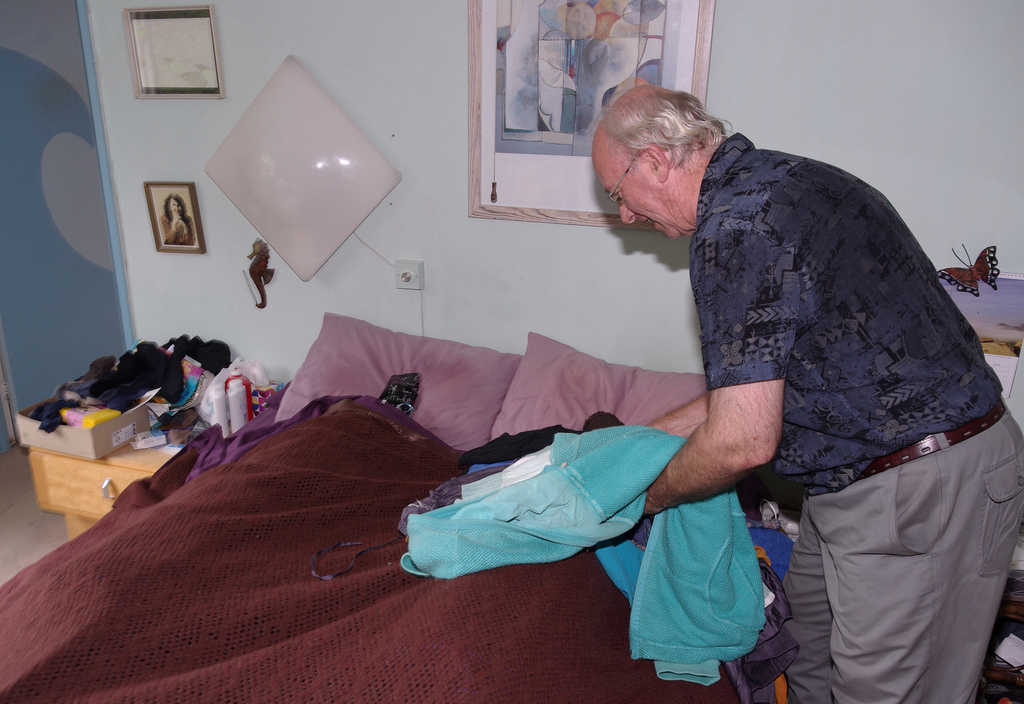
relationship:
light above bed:
[198, 57, 418, 274] [5, 293, 813, 701]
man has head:
[525, 76, 1020, 701] [577, 79, 724, 220]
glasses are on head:
[588, 157, 650, 209] [577, 79, 724, 220]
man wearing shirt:
[563, 84, 991, 696] [658, 133, 994, 478]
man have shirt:
[563, 84, 991, 696] [658, 133, 994, 478]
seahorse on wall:
[234, 230, 277, 304] [81, 12, 1018, 475]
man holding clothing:
[563, 84, 991, 696] [653, 155, 1005, 699]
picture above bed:
[463, 6, 719, 238] [5, 293, 813, 701]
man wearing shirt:
[563, 84, 991, 696] [658, 152, 1019, 472]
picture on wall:
[453, 5, 729, 253] [81, 12, 1018, 475]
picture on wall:
[109, 5, 233, 94] [81, 12, 1018, 475]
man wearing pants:
[569, 94, 1022, 664] [766, 446, 1011, 691]